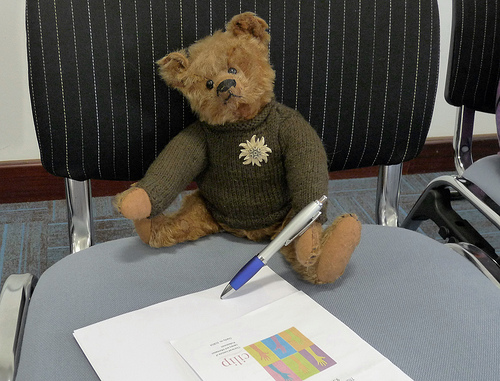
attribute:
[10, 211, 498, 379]
cushion — grey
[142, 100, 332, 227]
sweater — small, long sleeve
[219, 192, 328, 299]
pen — silver, blue ink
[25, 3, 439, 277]
chair — pinstriped, black, white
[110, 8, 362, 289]
bear — brown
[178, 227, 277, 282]
pen — blue, gray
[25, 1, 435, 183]
back — black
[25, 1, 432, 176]
stripes — white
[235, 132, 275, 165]
design — tan